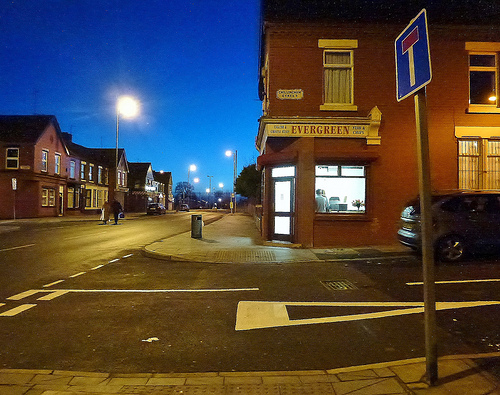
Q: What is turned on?
A: Street lights.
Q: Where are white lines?
A: On the street.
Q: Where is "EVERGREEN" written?
A: On white sign.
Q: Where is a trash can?
A: On sidewalk.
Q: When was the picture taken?
A: Almost night.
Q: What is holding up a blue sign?
A: A gray pole.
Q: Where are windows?
A: On the buildings.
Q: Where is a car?
A: On the road.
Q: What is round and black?
A: Car's tire.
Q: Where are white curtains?
A: Inside a window.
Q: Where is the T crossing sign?
A: Beside the road.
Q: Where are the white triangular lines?
A: On the street.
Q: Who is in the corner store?
A: People shopping.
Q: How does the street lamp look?
A: Turned on.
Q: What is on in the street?
A: Street Lights.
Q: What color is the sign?
A: Blue.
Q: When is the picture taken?
A: Nighttime.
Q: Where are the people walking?
A: Down the street.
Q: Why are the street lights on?
A: It is dark.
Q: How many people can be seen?
A: 2.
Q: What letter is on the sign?
A: T.